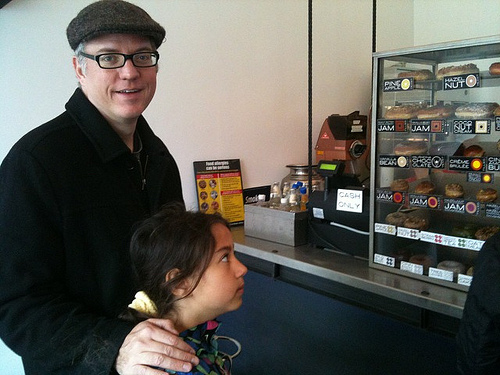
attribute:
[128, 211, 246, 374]
girl — looking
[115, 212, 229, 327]
hair — yellow, black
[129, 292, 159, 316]
scrunchie — yellow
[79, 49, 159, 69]
glasses — dark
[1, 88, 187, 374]
jacket — black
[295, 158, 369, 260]
cash register — black, cash register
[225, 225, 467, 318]
counter top — metal, silver, metallic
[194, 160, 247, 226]
sign — white, yellow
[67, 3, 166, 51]
hat — grey, black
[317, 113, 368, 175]
coffee grinder — brown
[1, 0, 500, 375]
wall — white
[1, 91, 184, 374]
sweatshirt — long sleeves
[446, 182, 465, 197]
donuts — brown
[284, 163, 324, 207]
vase — silver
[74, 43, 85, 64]
hair — grey